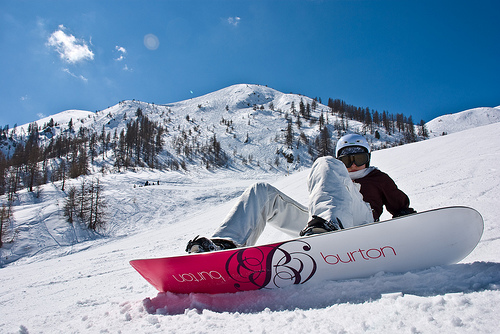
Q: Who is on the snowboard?
A: A snowboarder.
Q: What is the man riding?
A: A snowboard.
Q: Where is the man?
A: On the side of a mountain.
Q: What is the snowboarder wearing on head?
A: A helmet.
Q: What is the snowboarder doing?
A: Sitting in the snow.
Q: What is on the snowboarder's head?
A: A helmet.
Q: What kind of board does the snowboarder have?
A: Burton.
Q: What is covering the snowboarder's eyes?
A: Goggles.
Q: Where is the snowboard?
A: In the snow.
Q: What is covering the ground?
A: Snow.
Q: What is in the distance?
A: Mountains.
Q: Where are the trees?
A: On the mountain.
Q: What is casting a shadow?
A: The snowboard.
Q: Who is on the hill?
A: A man.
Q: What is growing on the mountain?
A: Green trees.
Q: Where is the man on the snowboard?
A: Next to a mountain covered in snow.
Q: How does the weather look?
A: Cold.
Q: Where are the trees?
A: Behind the person.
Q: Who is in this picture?
A: A snowboarder.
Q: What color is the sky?
A: Blue.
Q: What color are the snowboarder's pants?
A: White.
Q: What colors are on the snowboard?
A: Pink and white.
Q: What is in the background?
A: A mountain.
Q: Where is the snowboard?
A: Under the person.